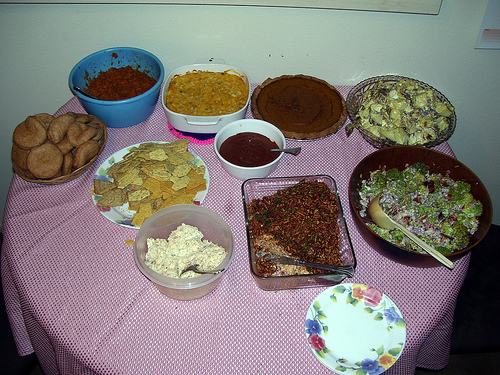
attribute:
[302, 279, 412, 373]
plates — paper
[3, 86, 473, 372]
table — round, one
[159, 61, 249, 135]
container — white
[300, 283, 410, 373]
plate — empty, paper , floral , white 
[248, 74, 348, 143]
pie — uneaten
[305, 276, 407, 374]
plate — paper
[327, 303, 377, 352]
plate center — white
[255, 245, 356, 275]
spoon —  metal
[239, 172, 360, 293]
dish — glass, clear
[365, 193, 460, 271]
server — plastic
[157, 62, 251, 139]
dish — white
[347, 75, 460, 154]
bowl —  round, glass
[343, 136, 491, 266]
bowl —  wooden, large, wooden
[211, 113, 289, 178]
bowl — round, white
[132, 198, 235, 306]
bowl — plastic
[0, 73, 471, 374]
table cloth — red, white, checkered, pink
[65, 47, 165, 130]
bowl — large, blue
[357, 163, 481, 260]
salad — plenty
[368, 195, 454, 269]
spoon — wooden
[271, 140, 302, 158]
spoon — silver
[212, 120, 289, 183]
bowl — white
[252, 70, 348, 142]
pie — one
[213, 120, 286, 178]
bowl — white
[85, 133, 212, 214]
chips — brown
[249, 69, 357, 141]
pie — brown, round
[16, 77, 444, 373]
cloth — checkered, red, table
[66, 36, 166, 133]
bowl — blue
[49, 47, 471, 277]
food — some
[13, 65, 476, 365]
table — one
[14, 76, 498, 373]
table — one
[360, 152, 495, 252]
food — some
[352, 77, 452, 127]
food — some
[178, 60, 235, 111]
food — some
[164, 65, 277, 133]
food — some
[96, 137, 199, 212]
food — some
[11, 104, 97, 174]
bread — some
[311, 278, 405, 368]
plate — one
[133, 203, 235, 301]
tub — plastic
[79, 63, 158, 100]
chili — red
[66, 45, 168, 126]
bowl — blue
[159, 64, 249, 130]
dish — white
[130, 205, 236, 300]
bowl — white